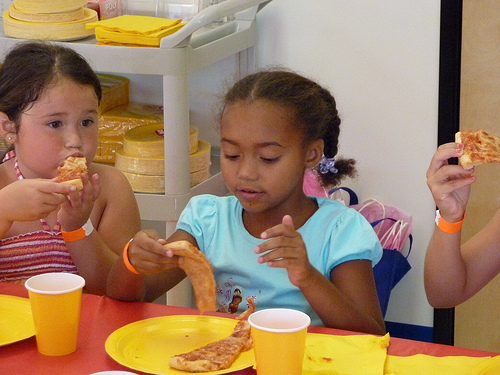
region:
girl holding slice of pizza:
[155, 229, 227, 318]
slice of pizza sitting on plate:
[175, 310, 259, 374]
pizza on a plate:
[100, 301, 255, 373]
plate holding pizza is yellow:
[99, 306, 263, 374]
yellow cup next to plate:
[241, 304, 318, 374]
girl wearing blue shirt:
[170, 185, 385, 331]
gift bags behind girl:
[305, 165, 410, 337]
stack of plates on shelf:
[106, 116, 214, 204]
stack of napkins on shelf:
[85, 7, 175, 58]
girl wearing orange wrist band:
[52, 220, 96, 246]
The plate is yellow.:
[111, 320, 171, 374]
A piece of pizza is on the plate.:
[100, 308, 247, 373]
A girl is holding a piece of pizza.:
[138, 232, 228, 318]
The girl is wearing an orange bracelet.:
[109, 228, 166, 278]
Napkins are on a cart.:
[83, 3, 305, 78]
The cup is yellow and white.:
[240, 305, 329, 373]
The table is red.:
[10, 357, 91, 372]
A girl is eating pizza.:
[34, 143, 132, 203]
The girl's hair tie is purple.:
[309, 144, 352, 186]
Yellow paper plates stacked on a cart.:
[110, 119, 218, 196]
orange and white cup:
[23, 273, 89, 356]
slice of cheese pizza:
[165, 240, 220, 311]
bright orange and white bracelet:
[430, 207, 470, 232]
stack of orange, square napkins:
[85, 11, 176, 46]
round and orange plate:
[0, 286, 35, 349]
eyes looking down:
[220, 145, 286, 165]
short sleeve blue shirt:
[172, 191, 383, 321]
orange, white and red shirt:
[0, 235, 95, 288]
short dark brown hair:
[2, 45, 102, 115]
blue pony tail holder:
[318, 153, 340, 181]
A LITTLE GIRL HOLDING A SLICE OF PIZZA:
[97, 63, 394, 340]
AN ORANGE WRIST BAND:
[431, 207, 467, 237]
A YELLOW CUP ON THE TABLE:
[21, 265, 88, 359]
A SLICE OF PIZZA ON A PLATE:
[103, 308, 275, 373]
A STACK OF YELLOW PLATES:
[113, 118, 214, 195]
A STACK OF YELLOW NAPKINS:
[84, 11, 181, 48]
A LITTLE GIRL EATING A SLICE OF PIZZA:
[3, 35, 145, 306]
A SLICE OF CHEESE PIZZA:
[165, 292, 265, 373]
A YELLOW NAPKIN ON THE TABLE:
[308, 324, 392, 371]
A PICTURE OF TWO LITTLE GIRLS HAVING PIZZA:
[5, 30, 405, 347]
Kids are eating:
[28, 44, 497, 344]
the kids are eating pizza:
[21, 44, 490, 294]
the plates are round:
[110, 276, 240, 355]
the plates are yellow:
[128, 266, 344, 371]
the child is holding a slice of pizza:
[23, 66, 456, 370]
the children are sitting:
[127, 168, 471, 365]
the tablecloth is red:
[93, 296, 113, 373]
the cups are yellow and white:
[253, 307, 320, 372]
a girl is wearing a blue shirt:
[193, 188, 358, 329]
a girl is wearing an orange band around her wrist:
[58, 218, 145, 248]